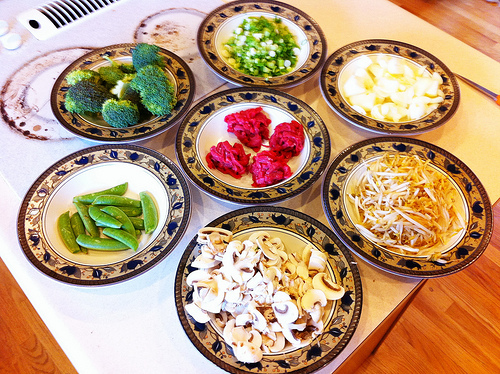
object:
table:
[0, 0, 499, 373]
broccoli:
[99, 95, 141, 129]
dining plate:
[195, 0, 328, 88]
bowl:
[15, 140, 196, 288]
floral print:
[17, 142, 194, 287]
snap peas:
[91, 193, 142, 209]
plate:
[171, 203, 364, 372]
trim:
[172, 202, 362, 373]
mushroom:
[310, 271, 346, 302]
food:
[223, 104, 273, 153]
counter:
[0, 0, 499, 374]